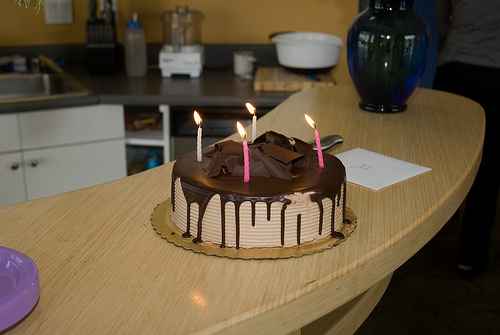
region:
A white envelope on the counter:
[321, 143, 431, 192]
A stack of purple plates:
[0, 242, 39, 334]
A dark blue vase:
[347, 0, 429, 121]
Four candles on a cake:
[190, 100, 325, 180]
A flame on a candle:
[234, 119, 250, 141]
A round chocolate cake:
[169, 130, 349, 247]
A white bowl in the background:
[270, 30, 345, 70]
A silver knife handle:
[307, 130, 344, 153]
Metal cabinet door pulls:
[10, 156, 39, 172]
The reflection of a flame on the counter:
[187, 289, 209, 307]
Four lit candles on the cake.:
[168, 87, 343, 252]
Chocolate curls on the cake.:
[206, 123, 295, 185]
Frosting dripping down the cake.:
[167, 185, 347, 255]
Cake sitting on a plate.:
[147, 132, 364, 270]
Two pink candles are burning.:
[229, 104, 330, 196]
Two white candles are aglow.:
[185, 91, 260, 158]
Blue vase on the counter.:
[335, 3, 449, 122]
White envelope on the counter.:
[335, 127, 435, 206]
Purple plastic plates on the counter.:
[1, 245, 54, 333]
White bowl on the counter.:
[267, 21, 344, 76]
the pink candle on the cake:
[240, 137, 251, 182]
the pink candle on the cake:
[312, 126, 324, 163]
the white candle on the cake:
[194, 124, 204, 159]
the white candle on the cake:
[250, 113, 257, 134]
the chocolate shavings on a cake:
[210, 134, 302, 175]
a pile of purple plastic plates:
[0, 241, 41, 327]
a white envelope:
[334, 145, 429, 188]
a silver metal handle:
[300, 133, 342, 150]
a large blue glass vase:
[348, 3, 426, 110]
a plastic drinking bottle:
[125, 12, 145, 77]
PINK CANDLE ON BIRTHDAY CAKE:
[230, 119, 254, 184]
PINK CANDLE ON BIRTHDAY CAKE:
[301, 112, 325, 169]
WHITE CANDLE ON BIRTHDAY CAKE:
[244, 102, 258, 142]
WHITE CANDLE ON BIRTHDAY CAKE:
[190, 107, 207, 163]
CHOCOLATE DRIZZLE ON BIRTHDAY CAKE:
[166, 132, 347, 246]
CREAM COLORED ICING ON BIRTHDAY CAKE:
[167, 179, 347, 248]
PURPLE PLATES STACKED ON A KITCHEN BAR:
[1, 242, 43, 334]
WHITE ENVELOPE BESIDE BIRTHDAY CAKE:
[336, 146, 431, 192]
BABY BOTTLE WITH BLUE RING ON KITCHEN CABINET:
[125, 11, 147, 75]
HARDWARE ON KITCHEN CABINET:
[28, 157, 41, 170]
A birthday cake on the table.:
[172, 99, 356, 248]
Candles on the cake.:
[188, 100, 321, 175]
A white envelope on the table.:
[342, 138, 425, 206]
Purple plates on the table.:
[1, 234, 61, 315]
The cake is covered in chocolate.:
[198, 128, 336, 193]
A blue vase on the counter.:
[333, 4, 438, 114]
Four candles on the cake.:
[191, 95, 345, 175]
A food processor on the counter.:
[154, 5, 212, 82]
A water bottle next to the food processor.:
[115, 5, 147, 81]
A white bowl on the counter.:
[263, 13, 348, 79]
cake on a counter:
[148, 88, 359, 264]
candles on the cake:
[153, 80, 338, 196]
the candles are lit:
[176, 87, 334, 190]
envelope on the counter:
[327, 127, 433, 202]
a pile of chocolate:
[190, 125, 297, 180]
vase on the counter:
[340, 5, 434, 125]